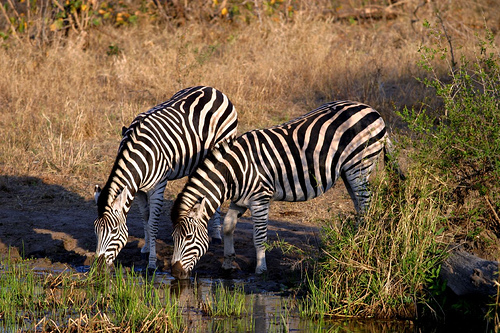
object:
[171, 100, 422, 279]
zebra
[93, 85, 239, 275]
zebra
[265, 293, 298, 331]
reflection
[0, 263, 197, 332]
mud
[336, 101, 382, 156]
butt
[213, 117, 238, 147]
stripe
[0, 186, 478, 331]
grass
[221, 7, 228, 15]
leaf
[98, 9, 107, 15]
leaf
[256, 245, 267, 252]
ankle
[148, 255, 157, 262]
ankle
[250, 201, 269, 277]
leg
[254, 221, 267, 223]
stripe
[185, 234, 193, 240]
eye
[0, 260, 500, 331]
water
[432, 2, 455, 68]
branch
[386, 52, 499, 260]
bush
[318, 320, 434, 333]
reflection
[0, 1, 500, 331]
meadow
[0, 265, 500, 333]
creek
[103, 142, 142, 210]
neck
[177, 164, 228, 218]
neck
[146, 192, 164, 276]
leg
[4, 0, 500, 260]
ground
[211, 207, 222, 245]
leg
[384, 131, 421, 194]
tail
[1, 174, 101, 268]
shadow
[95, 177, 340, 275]
shadow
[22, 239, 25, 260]
stalks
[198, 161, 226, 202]
stripe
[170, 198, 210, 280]
head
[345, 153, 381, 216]
back leg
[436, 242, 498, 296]
tree trunk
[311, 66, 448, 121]
shadow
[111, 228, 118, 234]
left eye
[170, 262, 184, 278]
nose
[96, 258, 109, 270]
nose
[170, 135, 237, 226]
mane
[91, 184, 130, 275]
head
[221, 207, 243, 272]
leg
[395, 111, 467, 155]
branch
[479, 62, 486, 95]
branch